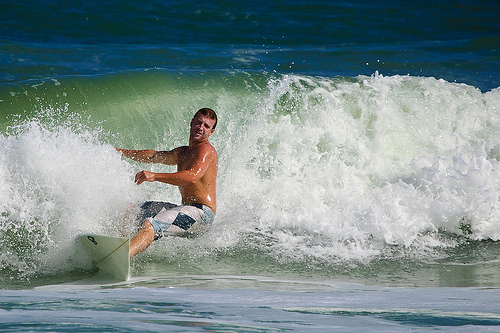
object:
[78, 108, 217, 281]
man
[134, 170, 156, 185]
hand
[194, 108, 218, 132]
hair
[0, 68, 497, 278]
rolling wave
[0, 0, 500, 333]
water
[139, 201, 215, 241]
short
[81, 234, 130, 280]
board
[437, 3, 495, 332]
right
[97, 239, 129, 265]
stripe